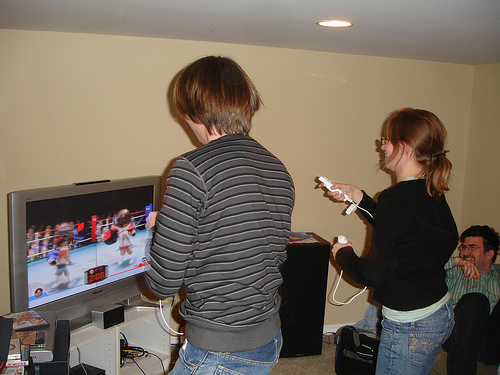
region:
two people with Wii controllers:
[130, 62, 437, 372]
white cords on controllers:
[333, 205, 372, 307]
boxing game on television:
[38, 189, 154, 291]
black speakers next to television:
[240, 229, 317, 371]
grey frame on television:
[17, 168, 169, 303]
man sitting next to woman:
[408, 211, 496, 363]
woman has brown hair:
[394, 95, 461, 194]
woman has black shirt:
[343, 164, 471, 329]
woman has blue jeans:
[372, 296, 477, 373]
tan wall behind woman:
[299, 84, 361, 159]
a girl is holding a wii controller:
[310, 102, 467, 374]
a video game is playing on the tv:
[6, 169, 167, 324]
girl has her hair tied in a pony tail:
[314, 103, 467, 373]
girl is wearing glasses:
[374, 101, 457, 206]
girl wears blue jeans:
[315, 102, 458, 374]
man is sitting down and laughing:
[441, 219, 499, 373]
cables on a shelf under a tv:
[116, 332, 166, 374]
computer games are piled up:
[5, 305, 59, 374]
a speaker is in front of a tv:
[89, 303, 128, 330]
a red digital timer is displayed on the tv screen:
[81, 263, 108, 289]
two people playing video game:
[118, 49, 460, 370]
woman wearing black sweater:
[366, 103, 462, 320]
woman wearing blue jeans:
[365, 105, 455, 374]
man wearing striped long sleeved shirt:
[156, 55, 286, 374]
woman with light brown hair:
[376, 107, 458, 194]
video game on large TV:
[11, 175, 166, 322]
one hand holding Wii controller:
[309, 170, 366, 230]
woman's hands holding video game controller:
[312, 167, 368, 303]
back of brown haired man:
[146, 50, 288, 370]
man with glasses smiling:
[458, 214, 498, 295]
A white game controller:
[316, 175, 353, 202]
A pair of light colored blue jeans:
[374, 296, 456, 374]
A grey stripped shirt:
[144, 132, 297, 352]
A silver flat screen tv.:
[6, 173, 163, 333]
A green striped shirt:
[445, 254, 499, 318]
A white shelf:
[68, 294, 172, 374]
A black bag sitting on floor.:
[332, 323, 380, 374]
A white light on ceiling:
[317, 18, 352, 27]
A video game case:
[0, 310, 50, 330]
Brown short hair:
[170, 55, 265, 135]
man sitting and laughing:
[443, 223, 499, 374]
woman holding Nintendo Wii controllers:
[314, 105, 456, 373]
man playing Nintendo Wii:
[143, 50, 293, 373]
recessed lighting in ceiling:
[315, 17, 354, 28]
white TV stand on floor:
[68, 305, 175, 374]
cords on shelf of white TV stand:
[119, 335, 164, 374]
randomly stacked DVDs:
[0, 310, 50, 373]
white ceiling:
[1, 0, 496, 66]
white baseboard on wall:
[318, 323, 353, 335]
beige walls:
[1, 28, 498, 323]